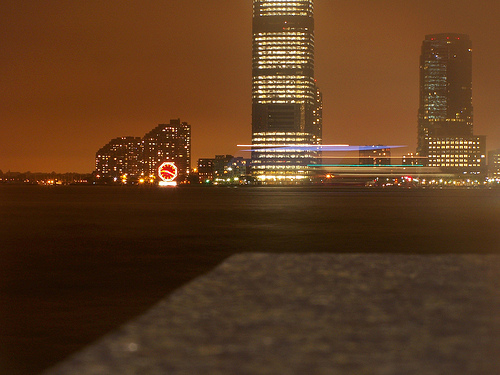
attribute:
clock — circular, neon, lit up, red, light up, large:
[151, 157, 180, 190]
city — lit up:
[2, 5, 499, 186]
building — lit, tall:
[249, 4, 318, 189]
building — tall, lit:
[414, 35, 482, 169]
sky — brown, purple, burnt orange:
[0, 1, 499, 169]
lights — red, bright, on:
[426, 32, 465, 43]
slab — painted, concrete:
[44, 249, 500, 373]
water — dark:
[2, 185, 498, 372]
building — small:
[143, 115, 194, 184]